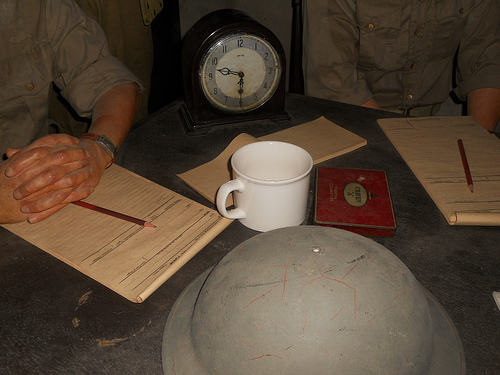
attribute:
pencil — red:
[68, 198, 162, 233]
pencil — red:
[449, 133, 479, 198]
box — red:
[324, 167, 388, 227]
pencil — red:
[73, 197, 157, 231]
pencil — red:
[455, 131, 475, 191]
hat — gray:
[160, 229, 467, 374]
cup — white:
[183, 122, 353, 229]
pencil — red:
[74, 199, 174, 243]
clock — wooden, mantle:
[177, 6, 294, 126]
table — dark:
[2, 63, 499, 370]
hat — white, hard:
[147, 229, 487, 371]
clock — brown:
[152, 22, 301, 127]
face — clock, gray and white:
[173, 17, 293, 116]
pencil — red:
[88, 200, 108, 215]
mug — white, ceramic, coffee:
[215, 140, 314, 235]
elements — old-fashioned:
[141, 200, 435, 302]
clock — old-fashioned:
[155, 7, 331, 126]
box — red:
[312, 167, 397, 234]